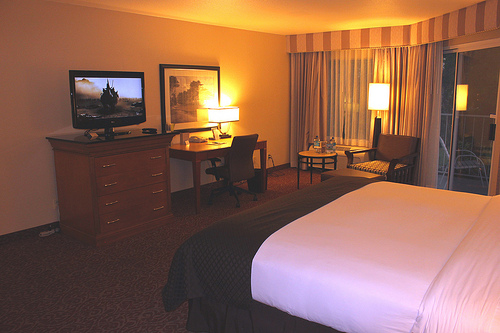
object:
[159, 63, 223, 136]
frame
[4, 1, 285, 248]
wall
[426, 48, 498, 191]
doors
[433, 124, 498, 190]
patio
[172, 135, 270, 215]
desk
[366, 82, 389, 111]
lamp shade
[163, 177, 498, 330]
bedding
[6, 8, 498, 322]
hotel room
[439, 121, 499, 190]
deck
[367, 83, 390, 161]
floor lamp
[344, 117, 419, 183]
armchair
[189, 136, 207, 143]
telephone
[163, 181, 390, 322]
bedskirt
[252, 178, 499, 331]
bedspread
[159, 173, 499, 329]
bed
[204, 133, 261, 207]
chair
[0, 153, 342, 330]
floor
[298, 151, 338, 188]
deck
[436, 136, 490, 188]
chair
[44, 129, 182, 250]
cabinets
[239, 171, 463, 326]
spread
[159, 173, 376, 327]
sheet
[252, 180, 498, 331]
sheet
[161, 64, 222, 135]
picture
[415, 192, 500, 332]
blanket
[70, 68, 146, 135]
television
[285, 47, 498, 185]
window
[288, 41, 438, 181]
curtain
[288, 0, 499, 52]
valance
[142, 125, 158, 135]
remote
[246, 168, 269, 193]
trash can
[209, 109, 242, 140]
lamp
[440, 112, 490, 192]
balcony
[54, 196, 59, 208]
outlet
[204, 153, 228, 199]
arms